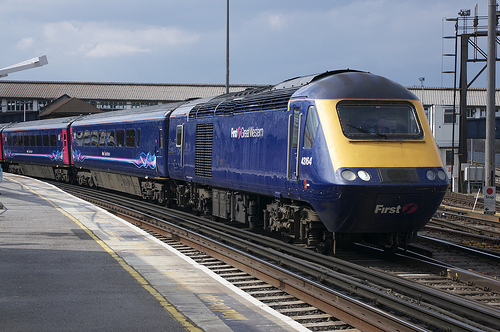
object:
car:
[74, 98, 181, 197]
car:
[4, 116, 73, 179]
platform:
[10, 181, 288, 328]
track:
[384, 230, 499, 294]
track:
[417, 199, 499, 246]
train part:
[308, 97, 443, 168]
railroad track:
[308, 259, 499, 330]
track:
[265, 227, 486, 314]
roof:
[0, 78, 270, 102]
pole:
[225, 0, 233, 87]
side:
[2, 103, 335, 181]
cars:
[167, 69, 452, 247]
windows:
[123, 123, 137, 147]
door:
[283, 98, 304, 181]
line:
[77, 184, 444, 328]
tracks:
[285, 254, 415, 311]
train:
[3, 70, 462, 256]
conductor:
[368, 112, 395, 137]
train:
[168, 69, 453, 255]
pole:
[454, 17, 470, 192]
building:
[0, 78, 498, 176]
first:
[372, 202, 402, 214]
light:
[436, 167, 448, 182]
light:
[426, 168, 436, 182]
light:
[357, 168, 372, 183]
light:
[338, 170, 355, 181]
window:
[330, 100, 426, 141]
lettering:
[228, 129, 234, 139]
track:
[60, 180, 497, 330]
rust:
[130, 211, 420, 330]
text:
[373, 203, 383, 214]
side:
[14, 99, 329, 221]